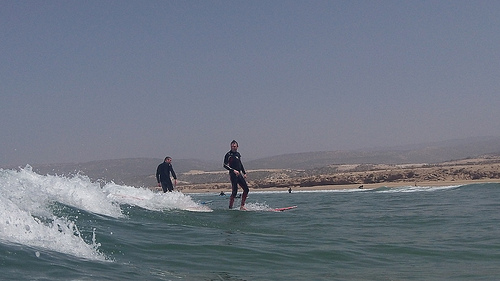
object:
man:
[223, 139, 254, 212]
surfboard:
[233, 204, 301, 211]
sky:
[2, 1, 498, 138]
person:
[413, 180, 418, 188]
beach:
[387, 180, 414, 187]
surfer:
[153, 154, 179, 191]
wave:
[108, 182, 163, 210]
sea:
[332, 192, 451, 235]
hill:
[341, 163, 388, 185]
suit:
[224, 152, 250, 201]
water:
[213, 235, 337, 268]